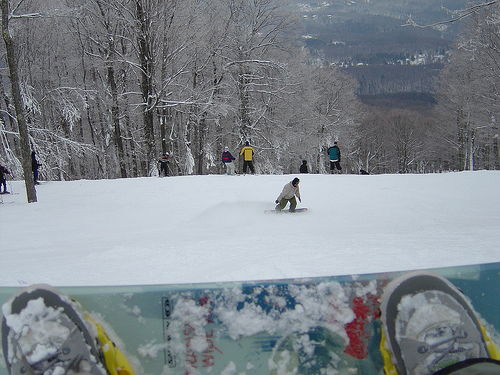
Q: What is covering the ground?
A: Snow.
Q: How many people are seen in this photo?
A: Five.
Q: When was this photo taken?
A: Daytime.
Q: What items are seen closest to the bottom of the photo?
A: Boots.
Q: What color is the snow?
A: White.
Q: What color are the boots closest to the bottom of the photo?
A: Grey.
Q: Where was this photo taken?
A: Ski slope.